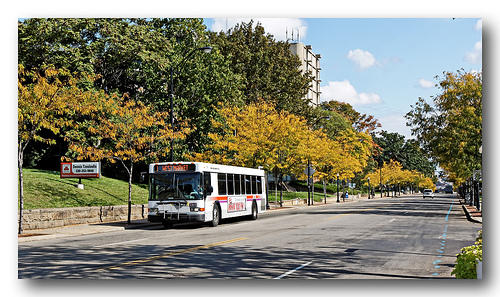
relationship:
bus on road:
[141, 166, 265, 223] [32, 194, 463, 292]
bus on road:
[141, 166, 265, 223] [21, 204, 463, 280]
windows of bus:
[220, 169, 266, 193] [141, 166, 265, 223]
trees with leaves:
[41, 32, 424, 186] [154, 85, 170, 94]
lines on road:
[130, 238, 248, 273] [32, 194, 463, 292]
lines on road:
[432, 206, 458, 270] [32, 194, 463, 292]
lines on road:
[281, 248, 328, 271] [32, 194, 463, 292]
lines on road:
[281, 248, 328, 271] [21, 204, 463, 280]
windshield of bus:
[150, 169, 204, 199] [141, 166, 265, 223]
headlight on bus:
[194, 206, 204, 215] [141, 166, 265, 223]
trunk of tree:
[126, 163, 133, 224] [107, 90, 149, 219]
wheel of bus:
[205, 204, 219, 223] [141, 166, 265, 223]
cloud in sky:
[347, 44, 373, 71] [286, 21, 499, 152]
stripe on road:
[268, 247, 307, 282] [32, 194, 463, 292]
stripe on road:
[124, 228, 238, 273] [32, 194, 463, 292]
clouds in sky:
[325, 50, 385, 104] [286, 21, 499, 152]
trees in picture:
[41, 32, 424, 186] [21, 28, 455, 268]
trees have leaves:
[41, 32, 424, 186] [154, 85, 170, 94]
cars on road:
[423, 190, 459, 210] [32, 194, 463, 292]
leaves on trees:
[154, 85, 170, 94] [41, 32, 424, 186]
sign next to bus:
[62, 156, 103, 177] [141, 166, 265, 223]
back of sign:
[303, 164, 318, 181] [305, 164, 317, 175]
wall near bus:
[28, 203, 133, 223] [141, 166, 265, 223]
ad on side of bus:
[227, 194, 249, 211] [141, 166, 265, 223]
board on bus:
[151, 166, 199, 173] [141, 166, 265, 223]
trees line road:
[41, 32, 424, 186] [21, 204, 463, 280]